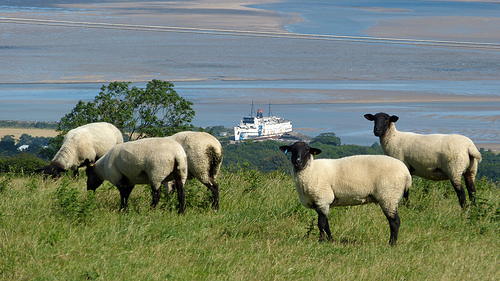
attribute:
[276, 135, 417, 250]
sheep — black, white, gazig, gazing, standing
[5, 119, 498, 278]
field — green, thick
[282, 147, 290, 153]
tag — blue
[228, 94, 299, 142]
ship — white, big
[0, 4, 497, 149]
water — blue, brown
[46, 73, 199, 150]
tree — green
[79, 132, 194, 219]
sheep — black, white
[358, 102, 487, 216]
sheep — black, white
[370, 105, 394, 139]
face — black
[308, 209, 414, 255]
legs — black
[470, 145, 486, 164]
hair — short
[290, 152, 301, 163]
hose — black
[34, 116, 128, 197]
sheep — black, white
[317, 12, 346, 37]
sky — blue